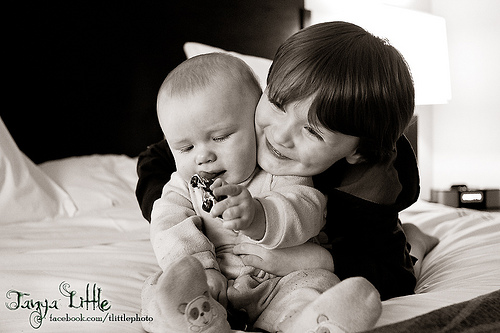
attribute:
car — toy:
[193, 172, 227, 212]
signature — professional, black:
[4, 282, 111, 329]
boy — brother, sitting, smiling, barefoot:
[152, 51, 383, 333]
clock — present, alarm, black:
[434, 185, 500, 210]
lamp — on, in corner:
[319, 2, 452, 105]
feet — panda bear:
[152, 262, 228, 332]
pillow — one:
[184, 44, 281, 94]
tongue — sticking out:
[198, 172, 214, 180]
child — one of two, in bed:
[138, 24, 420, 300]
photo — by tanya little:
[4, 2, 499, 332]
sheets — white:
[0, 154, 496, 328]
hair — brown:
[265, 23, 417, 163]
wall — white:
[305, 1, 497, 206]